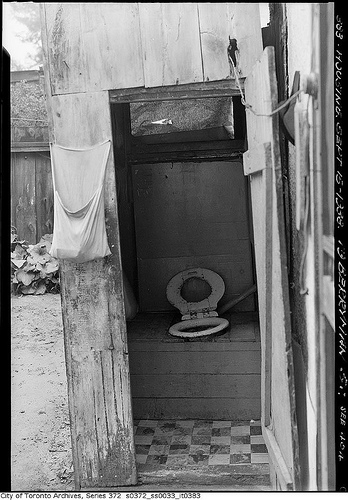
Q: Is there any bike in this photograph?
A: No, there are no bikes.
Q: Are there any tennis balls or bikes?
A: No, there are no bikes or tennis balls.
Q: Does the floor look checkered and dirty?
A: Yes, the floor is checkered and dirty.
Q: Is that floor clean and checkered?
A: No, the floor is checkered but dirty.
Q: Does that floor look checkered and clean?
A: No, the floor is checkered but dirty.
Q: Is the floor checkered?
A: Yes, the floor is checkered.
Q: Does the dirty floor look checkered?
A: Yes, the floor is checkered.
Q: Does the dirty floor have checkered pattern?
A: Yes, the floor is checkered.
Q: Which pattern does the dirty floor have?
A: The floor has checkered pattern.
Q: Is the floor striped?
A: No, the floor is checkered.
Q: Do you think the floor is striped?
A: No, the floor is checkered.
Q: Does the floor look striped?
A: No, the floor is checkered.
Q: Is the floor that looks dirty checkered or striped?
A: The floor is checkered.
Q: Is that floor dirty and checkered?
A: Yes, the floor is dirty and checkered.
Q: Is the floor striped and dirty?
A: No, the floor is dirty but checkered.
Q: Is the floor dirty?
A: Yes, the floor is dirty.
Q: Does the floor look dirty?
A: Yes, the floor is dirty.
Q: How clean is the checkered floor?
A: The floor is dirty.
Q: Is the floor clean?
A: No, the floor is dirty.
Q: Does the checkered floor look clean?
A: No, the floor is dirty.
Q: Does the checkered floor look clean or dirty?
A: The floor is dirty.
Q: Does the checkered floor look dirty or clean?
A: The floor is dirty.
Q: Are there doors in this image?
A: Yes, there is a door.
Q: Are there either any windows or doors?
A: Yes, there is a door.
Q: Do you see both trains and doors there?
A: No, there is a door but no trains.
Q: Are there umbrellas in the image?
A: No, there are no umbrellas.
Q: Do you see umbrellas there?
A: No, there are no umbrellas.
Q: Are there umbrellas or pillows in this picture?
A: No, there are no umbrellas or pillows.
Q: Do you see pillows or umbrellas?
A: No, there are no umbrellas or pillows.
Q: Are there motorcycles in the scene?
A: No, there are no motorcycles.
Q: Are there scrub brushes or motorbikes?
A: No, there are no motorbikes or scrub brushes.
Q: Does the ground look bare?
A: Yes, the ground is bare.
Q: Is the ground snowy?
A: No, the ground is bare.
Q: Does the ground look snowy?
A: No, the ground is bare.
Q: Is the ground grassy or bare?
A: The ground is bare.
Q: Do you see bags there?
A: Yes, there is a bag.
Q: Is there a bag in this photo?
A: Yes, there is a bag.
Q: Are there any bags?
A: Yes, there is a bag.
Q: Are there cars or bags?
A: Yes, there is a bag.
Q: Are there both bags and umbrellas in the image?
A: No, there is a bag but no umbrellas.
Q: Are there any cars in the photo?
A: No, there are no cars.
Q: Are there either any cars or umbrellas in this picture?
A: No, there are no cars or umbrellas.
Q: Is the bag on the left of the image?
A: Yes, the bag is on the left of the image.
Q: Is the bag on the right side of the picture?
A: No, the bag is on the left of the image.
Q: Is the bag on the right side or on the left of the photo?
A: The bag is on the left of the image.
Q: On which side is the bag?
A: The bag is on the left of the image.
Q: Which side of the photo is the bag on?
A: The bag is on the left of the image.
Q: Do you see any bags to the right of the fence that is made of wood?
A: Yes, there is a bag to the right of the fence.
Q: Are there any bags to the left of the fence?
A: No, the bag is to the right of the fence.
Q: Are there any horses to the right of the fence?
A: No, there is a bag to the right of the fence.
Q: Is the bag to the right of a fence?
A: Yes, the bag is to the right of a fence.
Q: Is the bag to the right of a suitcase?
A: No, the bag is to the right of a fence.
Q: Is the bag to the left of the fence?
A: No, the bag is to the right of the fence.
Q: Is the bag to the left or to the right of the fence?
A: The bag is to the right of the fence.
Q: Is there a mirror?
A: No, there are no mirrors.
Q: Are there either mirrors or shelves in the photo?
A: No, there are no mirrors or shelves.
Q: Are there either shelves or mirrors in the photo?
A: No, there are no mirrors or shelves.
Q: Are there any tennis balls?
A: No, there are no tennis balls.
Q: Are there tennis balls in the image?
A: No, there are no tennis balls.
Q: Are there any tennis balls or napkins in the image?
A: No, there are no tennis balls or napkins.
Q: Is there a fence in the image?
A: Yes, there is a fence.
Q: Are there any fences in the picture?
A: Yes, there is a fence.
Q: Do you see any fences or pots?
A: Yes, there is a fence.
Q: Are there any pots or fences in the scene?
A: Yes, there is a fence.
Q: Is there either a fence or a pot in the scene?
A: Yes, there is a fence.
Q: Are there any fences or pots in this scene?
A: Yes, there is a fence.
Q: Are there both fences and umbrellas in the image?
A: No, there is a fence but no umbrellas.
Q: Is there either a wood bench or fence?
A: Yes, there is a wood fence.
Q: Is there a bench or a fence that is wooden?
A: Yes, the fence is wooden.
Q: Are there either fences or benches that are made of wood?
A: Yes, the fence is made of wood.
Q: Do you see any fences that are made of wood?
A: Yes, there is a fence that is made of wood.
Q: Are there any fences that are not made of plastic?
A: Yes, there is a fence that is made of wood.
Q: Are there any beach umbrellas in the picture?
A: No, there are no beach umbrellas.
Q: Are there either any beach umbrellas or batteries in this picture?
A: No, there are no beach umbrellas or batteries.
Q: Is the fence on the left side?
A: Yes, the fence is on the left of the image.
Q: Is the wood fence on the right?
A: No, the fence is on the left of the image.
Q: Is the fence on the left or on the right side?
A: The fence is on the left of the image.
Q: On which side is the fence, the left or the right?
A: The fence is on the left of the image.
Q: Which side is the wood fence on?
A: The fence is on the left of the image.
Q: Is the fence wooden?
A: Yes, the fence is wooden.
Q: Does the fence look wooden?
A: Yes, the fence is wooden.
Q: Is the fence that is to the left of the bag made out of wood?
A: Yes, the fence is made of wood.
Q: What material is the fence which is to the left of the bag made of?
A: The fence is made of wood.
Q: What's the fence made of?
A: The fence is made of wood.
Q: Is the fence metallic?
A: No, the fence is wooden.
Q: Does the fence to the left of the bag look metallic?
A: No, the fence is wooden.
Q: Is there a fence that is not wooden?
A: No, there is a fence but it is wooden.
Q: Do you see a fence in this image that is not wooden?
A: No, there is a fence but it is wooden.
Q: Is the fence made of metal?
A: No, the fence is made of wood.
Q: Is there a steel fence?
A: No, there is a fence but it is made of wood.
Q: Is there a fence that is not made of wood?
A: No, there is a fence but it is made of wood.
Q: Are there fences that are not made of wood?
A: No, there is a fence but it is made of wood.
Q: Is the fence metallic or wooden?
A: The fence is wooden.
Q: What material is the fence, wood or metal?
A: The fence is made of wood.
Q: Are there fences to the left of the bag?
A: Yes, there is a fence to the left of the bag.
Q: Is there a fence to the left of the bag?
A: Yes, there is a fence to the left of the bag.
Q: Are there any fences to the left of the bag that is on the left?
A: Yes, there is a fence to the left of the bag.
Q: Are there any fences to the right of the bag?
A: No, the fence is to the left of the bag.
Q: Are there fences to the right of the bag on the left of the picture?
A: No, the fence is to the left of the bag.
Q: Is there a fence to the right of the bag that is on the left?
A: No, the fence is to the left of the bag.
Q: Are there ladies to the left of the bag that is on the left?
A: No, there is a fence to the left of the bag.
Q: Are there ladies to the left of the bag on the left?
A: No, there is a fence to the left of the bag.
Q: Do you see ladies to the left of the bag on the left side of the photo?
A: No, there is a fence to the left of the bag.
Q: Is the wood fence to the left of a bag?
A: Yes, the fence is to the left of a bag.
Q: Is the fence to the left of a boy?
A: No, the fence is to the left of a bag.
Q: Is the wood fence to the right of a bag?
A: No, the fence is to the left of a bag.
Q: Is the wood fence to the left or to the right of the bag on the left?
A: The fence is to the left of the bag.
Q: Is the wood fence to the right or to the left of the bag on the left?
A: The fence is to the left of the bag.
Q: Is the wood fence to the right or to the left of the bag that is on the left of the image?
A: The fence is to the left of the bag.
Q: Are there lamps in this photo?
A: No, there are no lamps.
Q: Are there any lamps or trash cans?
A: No, there are no lamps or trash cans.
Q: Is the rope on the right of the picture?
A: Yes, the rope is on the right of the image.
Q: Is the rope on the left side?
A: No, the rope is on the right of the image.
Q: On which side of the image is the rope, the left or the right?
A: The rope is on the right of the image.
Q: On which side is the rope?
A: The rope is on the right of the image.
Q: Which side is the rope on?
A: The rope is on the right of the image.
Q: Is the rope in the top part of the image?
A: Yes, the rope is in the top of the image.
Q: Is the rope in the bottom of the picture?
A: No, the rope is in the top of the image.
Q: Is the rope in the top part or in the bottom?
A: The rope is in the top of the image.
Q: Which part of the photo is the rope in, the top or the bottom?
A: The rope is in the top of the image.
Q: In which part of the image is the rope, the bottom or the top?
A: The rope is in the top of the image.